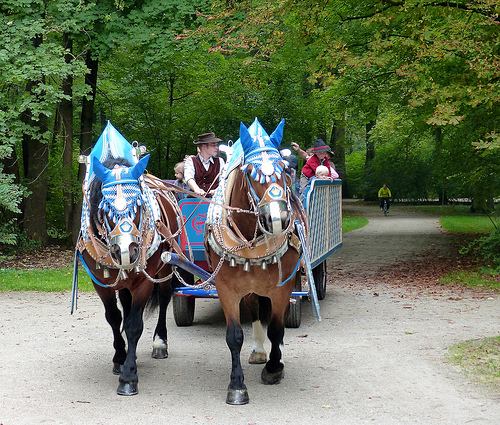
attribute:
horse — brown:
[70, 150, 189, 398]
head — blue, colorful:
[86, 153, 158, 274]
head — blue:
[231, 121, 302, 234]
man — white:
[179, 127, 229, 196]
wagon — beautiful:
[173, 174, 347, 333]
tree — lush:
[300, 7, 402, 197]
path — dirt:
[5, 195, 494, 424]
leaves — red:
[324, 230, 488, 306]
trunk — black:
[324, 114, 358, 202]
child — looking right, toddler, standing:
[293, 143, 340, 205]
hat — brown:
[191, 126, 226, 144]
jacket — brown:
[188, 155, 220, 191]